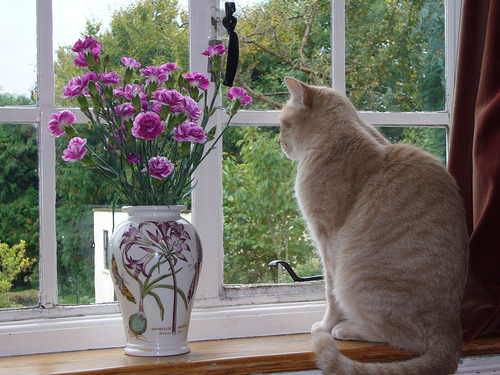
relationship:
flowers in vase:
[46, 35, 252, 181] [93, 196, 219, 361]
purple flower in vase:
[137, 152, 174, 204] [105, 202, 205, 356]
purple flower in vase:
[169, 115, 206, 205] [105, 202, 205, 356]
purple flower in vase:
[177, 67, 208, 204] [105, 202, 205, 356]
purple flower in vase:
[126, 108, 164, 203] [105, 202, 205, 356]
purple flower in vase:
[56, 135, 133, 206] [105, 202, 205, 356]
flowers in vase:
[46, 35, 252, 181] [112, 199, 197, 355]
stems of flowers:
[88, 95, 230, 213] [46, 35, 252, 181]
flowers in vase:
[46, 35, 252, 181] [105, 202, 205, 356]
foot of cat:
[328, 316, 356, 338] [250, 68, 484, 373]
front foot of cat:
[306, 282, 333, 338] [250, 68, 484, 373]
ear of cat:
[280, 71, 317, 110] [250, 68, 484, 373]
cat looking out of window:
[278, 76, 469, 375] [0, 4, 465, 335]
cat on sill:
[250, 68, 484, 373] [203, 339, 347, 359]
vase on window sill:
[105, 202, 205, 356] [112, 338, 203, 363]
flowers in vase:
[46, 39, 226, 193] [99, 193, 220, 373]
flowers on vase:
[106, 204, 202, 356] [105, 202, 205, 356]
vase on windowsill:
[105, 202, 205, 356] [2, 301, 499, 373]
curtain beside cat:
[444, 0, 498, 339] [250, 68, 484, 373]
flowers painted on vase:
[99, 193, 227, 371] [105, 202, 205, 356]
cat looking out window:
[250, 68, 484, 373] [6, 7, 498, 374]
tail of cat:
[306, 329, 461, 374] [274, 65, 486, 374]